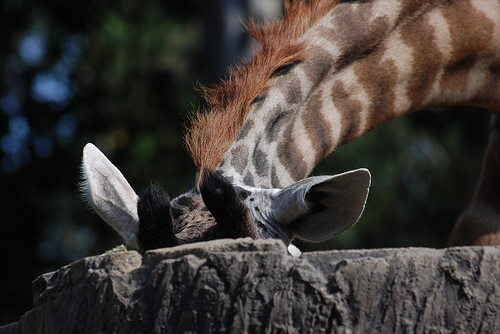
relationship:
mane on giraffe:
[183, 10, 284, 165] [74, 7, 482, 252]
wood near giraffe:
[8, 240, 491, 332] [74, 7, 482, 252]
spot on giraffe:
[333, 78, 367, 141] [75, 6, 477, 228]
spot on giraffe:
[254, 145, 265, 175] [74, 7, 482, 252]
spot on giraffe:
[403, 13, 439, 118] [74, 7, 482, 252]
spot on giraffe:
[299, 40, 336, 90] [75, 6, 477, 228]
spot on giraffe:
[403, 13, 439, 118] [75, 6, 477, 228]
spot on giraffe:
[272, 67, 320, 107] [74, 7, 482, 252]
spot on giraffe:
[327, 7, 383, 57] [74, 7, 482, 252]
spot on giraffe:
[274, 127, 309, 176] [74, 7, 482, 252]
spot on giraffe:
[442, 8, 483, 68] [74, 7, 482, 252]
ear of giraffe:
[79, 142, 165, 244] [74, 7, 482, 252]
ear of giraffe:
[272, 166, 379, 239] [74, 7, 482, 252]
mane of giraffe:
[183, 10, 373, 160] [74, 7, 482, 252]